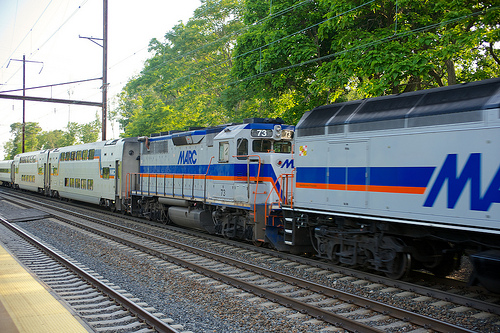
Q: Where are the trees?
A: Behind train.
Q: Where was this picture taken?
A: A train track.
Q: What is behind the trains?
A: Trees.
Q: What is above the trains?
A: Power lines.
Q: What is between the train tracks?
A: Gravel.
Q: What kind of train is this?
A: A passenger train.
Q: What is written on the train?
A: MARC.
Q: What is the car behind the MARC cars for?
A: Holding passengers.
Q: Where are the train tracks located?
A: On the ground.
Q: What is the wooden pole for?
A: Holding up the power lines.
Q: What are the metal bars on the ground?
A: Train tracks.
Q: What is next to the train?
A: Green leafy trees.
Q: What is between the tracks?
A: Gray gravels.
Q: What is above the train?
A: A power line.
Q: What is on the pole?
A: Power lines.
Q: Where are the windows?
A: There are two rows of windows on each car.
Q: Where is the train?
A: On the train tracks.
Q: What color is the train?
A: Blue and silver.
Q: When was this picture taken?
A: Daytime.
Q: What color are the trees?
A: Green.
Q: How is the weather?
A: Sunny.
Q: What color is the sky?
A: White.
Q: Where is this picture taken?
A: The railway.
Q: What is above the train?
A: Power lines.